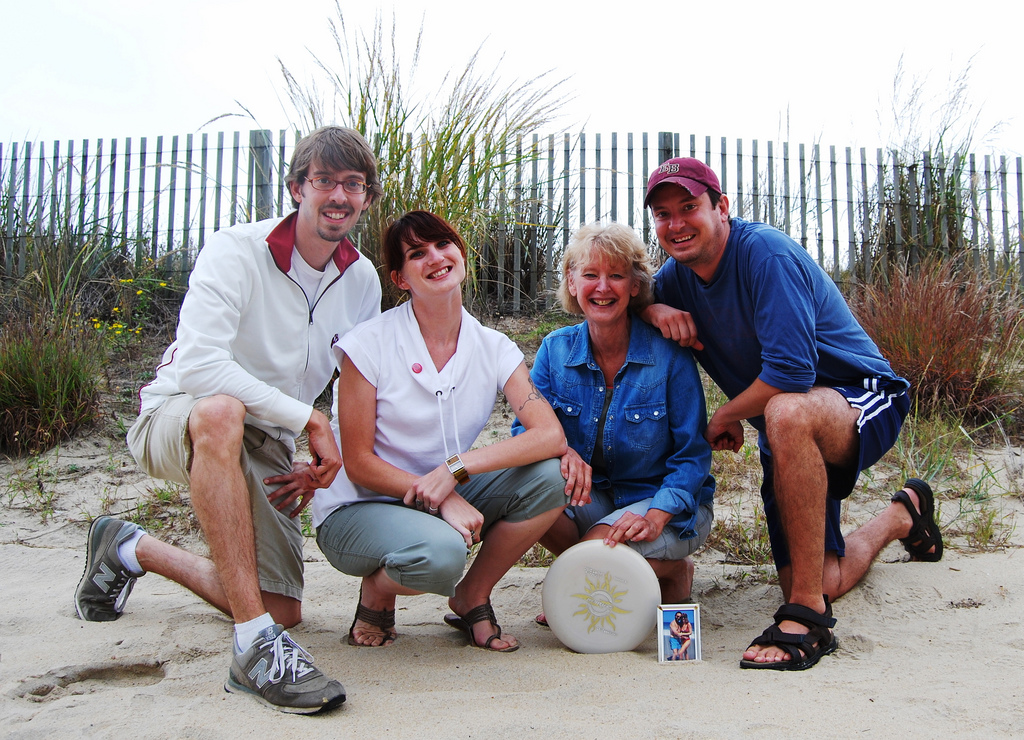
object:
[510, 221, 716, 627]
person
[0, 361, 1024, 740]
beach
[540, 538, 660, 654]
frisbee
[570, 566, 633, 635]
design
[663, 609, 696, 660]
picture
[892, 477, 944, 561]
sandal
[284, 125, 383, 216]
hair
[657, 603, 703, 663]
cap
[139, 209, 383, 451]
jacket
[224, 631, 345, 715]
silver n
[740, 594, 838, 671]
brown shoe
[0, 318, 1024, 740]
ground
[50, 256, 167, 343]
flowers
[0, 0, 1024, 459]
trees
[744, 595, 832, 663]
feet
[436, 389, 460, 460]
strings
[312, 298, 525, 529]
shirt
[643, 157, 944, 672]
man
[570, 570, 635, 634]
sun graphic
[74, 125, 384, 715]
man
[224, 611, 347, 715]
foot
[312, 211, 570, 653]
person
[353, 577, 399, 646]
foot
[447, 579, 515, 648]
foot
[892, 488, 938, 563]
foot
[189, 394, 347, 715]
leg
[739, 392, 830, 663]
leg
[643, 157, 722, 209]
hat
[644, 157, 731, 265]
head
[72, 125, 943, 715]
people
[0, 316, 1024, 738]
sand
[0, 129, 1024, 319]
fence